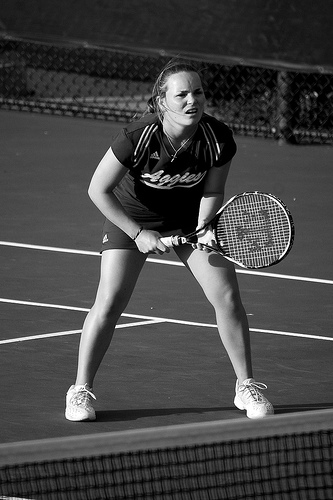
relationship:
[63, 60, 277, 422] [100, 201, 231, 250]
woman wearing shorts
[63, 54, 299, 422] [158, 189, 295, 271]
woman holding racket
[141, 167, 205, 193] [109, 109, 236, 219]
aggies on shirt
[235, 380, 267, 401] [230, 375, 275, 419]
laces on tennis shoe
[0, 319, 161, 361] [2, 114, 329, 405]
line on tennis court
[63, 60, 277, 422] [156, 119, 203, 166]
woman wearing necklace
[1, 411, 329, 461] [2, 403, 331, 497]
trim on tennis net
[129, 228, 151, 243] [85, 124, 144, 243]
band on arm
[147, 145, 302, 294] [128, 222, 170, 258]
racket in hand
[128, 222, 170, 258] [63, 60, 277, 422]
hand of woman